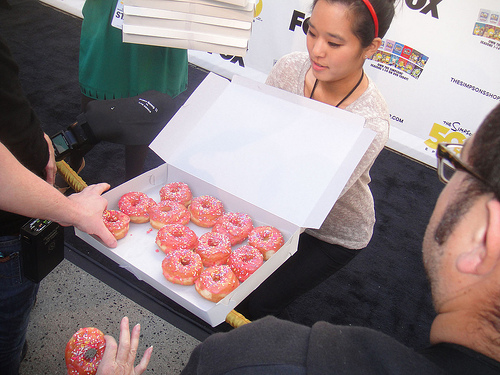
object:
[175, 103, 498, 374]
man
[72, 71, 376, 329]
box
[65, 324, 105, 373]
donut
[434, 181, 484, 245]
sideburn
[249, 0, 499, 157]
banner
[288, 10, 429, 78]
advert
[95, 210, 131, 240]
donut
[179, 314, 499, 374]
shirt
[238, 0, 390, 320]
woman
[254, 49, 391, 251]
shirt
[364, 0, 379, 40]
headband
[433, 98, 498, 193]
hair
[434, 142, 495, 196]
glasses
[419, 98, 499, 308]
head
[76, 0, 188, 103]
dress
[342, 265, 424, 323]
floor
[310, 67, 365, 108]
string